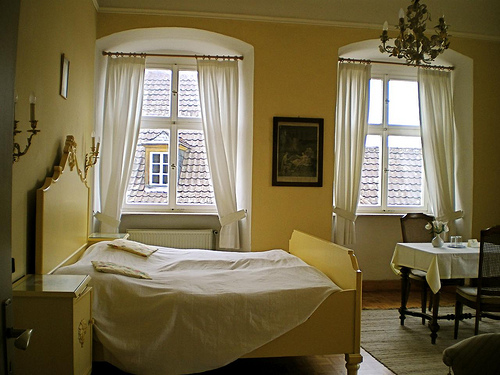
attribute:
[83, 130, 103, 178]
light — fancy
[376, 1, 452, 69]
light — hanging, gold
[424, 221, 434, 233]
rose — white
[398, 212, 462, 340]
chair — black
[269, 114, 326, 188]
picture — framed, hanging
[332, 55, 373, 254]
curtain — white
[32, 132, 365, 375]
bed — made, white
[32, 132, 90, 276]
headboard — fancy, wooden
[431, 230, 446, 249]
vase — white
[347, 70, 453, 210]
window — in room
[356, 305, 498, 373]
rug — green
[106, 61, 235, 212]
window — in room